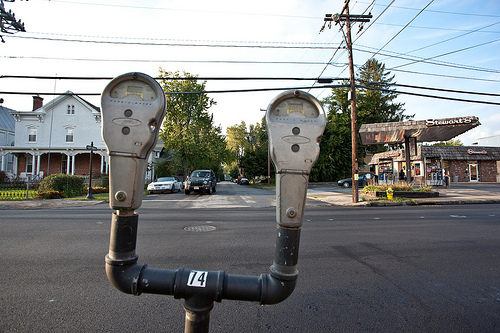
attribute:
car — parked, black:
[338, 171, 374, 190]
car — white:
[143, 172, 180, 194]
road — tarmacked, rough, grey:
[151, 165, 327, 212]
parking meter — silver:
[99, 70, 164, 210]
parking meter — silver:
[266, 89, 328, 228]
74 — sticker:
[187, 269, 208, 291]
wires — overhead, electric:
[3, 3, 499, 106]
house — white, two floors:
[1, 89, 108, 190]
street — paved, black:
[3, 200, 499, 332]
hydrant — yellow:
[386, 183, 397, 203]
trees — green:
[160, 73, 276, 176]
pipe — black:
[106, 212, 297, 330]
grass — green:
[2, 186, 44, 203]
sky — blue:
[5, 0, 499, 119]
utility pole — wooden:
[324, 0, 375, 199]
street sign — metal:
[85, 142, 100, 202]